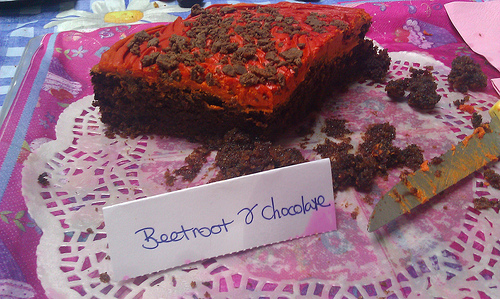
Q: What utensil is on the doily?
A: A knife.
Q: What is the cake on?
A: A doily.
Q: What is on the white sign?
A: Beetroot & Chocolate.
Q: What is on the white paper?
A: Blue writing.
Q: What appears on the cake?
A: Red frosting.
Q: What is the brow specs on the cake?
A: Chocolate chips.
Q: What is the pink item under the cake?
A: A tray.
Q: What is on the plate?
A: A white doiley.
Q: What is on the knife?
A: Orange frosting.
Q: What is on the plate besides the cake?
A: A sign.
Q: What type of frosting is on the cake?
A: Orange frosting.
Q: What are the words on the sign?
A: *Beetroot & Chocolate".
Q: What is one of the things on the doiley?
A: The chocolate cake.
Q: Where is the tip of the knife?
A: On the table.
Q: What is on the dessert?
A: Red frosting.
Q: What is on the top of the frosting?
A: Chocolate shavings.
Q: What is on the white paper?
A: Blue writing.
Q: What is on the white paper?
A: The type of dessert.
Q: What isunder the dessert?
A: A doily.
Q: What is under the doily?
A: A cloth.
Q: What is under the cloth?
A: A table cloth.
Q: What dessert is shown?
A: Cake.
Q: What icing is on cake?
A: Chocolate.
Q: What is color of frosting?
A: Red.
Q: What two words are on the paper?
A: "Beetroot" and "chocolate".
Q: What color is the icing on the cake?
A: Red.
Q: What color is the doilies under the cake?
A: White.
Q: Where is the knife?
A: To the right of the cake.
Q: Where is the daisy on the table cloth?
A: Behind the cake.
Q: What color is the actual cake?
A: Brown.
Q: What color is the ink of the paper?
A: Blue.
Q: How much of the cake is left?
A: A quarter.